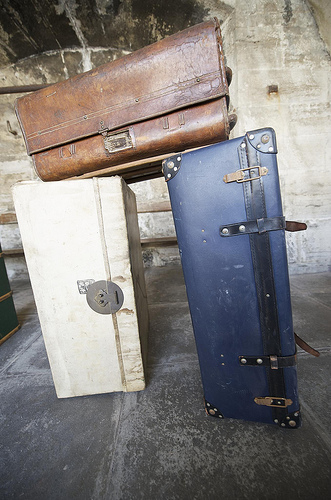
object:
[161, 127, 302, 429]
suitcase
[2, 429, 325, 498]
ground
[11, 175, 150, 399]
suitcase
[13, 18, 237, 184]
suitcase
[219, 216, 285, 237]
strap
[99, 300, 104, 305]
keyhole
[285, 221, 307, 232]
strap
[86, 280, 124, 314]
clasp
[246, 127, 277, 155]
corner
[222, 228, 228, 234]
rivet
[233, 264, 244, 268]
mark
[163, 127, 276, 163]
top